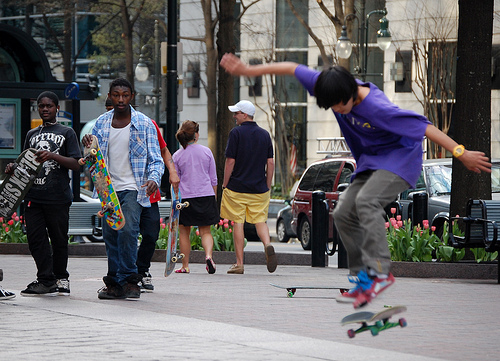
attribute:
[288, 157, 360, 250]
minivan — small , red 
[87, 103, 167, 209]
shirt — blue, plaid, long sleeve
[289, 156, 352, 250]
car — red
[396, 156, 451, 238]
car — silver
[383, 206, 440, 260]
flowers — pink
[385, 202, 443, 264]
flowers — bloom, leafy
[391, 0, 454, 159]
tree — bare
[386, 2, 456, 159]
tree — leafless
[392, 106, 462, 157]
arm — boy's, outstretched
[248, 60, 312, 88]
arm — boy's, outstretched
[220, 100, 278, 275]
man — walking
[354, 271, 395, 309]
sneaker — red and white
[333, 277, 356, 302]
sneaker — red and white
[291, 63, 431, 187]
tee shirt — cotton, blue, purple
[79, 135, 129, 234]
skate board — printed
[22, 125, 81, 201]
tee shirt — black and white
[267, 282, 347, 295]
skate board — skate 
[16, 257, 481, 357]
side wide — side 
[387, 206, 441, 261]
pink flowers — pink 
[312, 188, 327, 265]
metal pole — black , metal 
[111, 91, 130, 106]
admiring look — astonished , admiring 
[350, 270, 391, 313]
sneakers — red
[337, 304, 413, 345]
board — green, metal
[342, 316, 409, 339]
wheels — reddish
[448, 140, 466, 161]
watch — yellow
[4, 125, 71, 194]
t-shirt — black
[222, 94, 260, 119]
cap — white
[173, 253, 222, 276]
shoes — flat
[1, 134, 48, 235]
skateboard — black